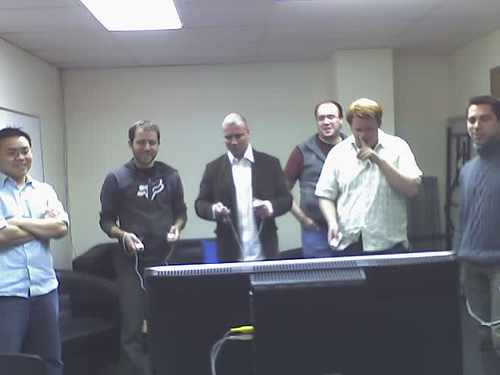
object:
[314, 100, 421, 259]
man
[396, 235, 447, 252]
ground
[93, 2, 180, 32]
light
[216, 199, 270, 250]
viedo controller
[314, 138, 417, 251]
shirt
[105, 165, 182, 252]
shirt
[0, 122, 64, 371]
man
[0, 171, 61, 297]
shirt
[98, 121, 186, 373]
man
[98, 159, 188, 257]
hoodie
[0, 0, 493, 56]
ceiling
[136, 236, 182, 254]
controller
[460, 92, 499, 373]
man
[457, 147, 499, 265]
blue sweater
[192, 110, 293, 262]
man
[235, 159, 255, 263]
white shirt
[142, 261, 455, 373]
tv screen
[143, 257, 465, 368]
computer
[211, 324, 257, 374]
cord